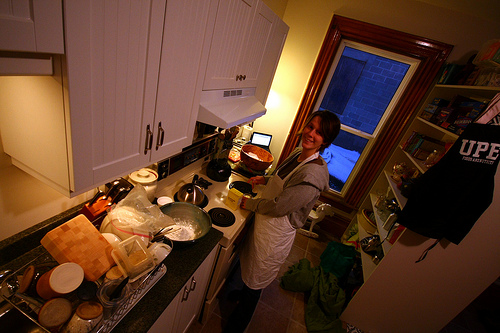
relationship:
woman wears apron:
[224, 105, 342, 332] [237, 144, 321, 289]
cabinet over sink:
[255, 15, 290, 105] [1, 295, 40, 330]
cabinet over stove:
[255, 15, 290, 105] [161, 158, 262, 233]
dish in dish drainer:
[36, 259, 84, 295] [0, 247, 167, 332]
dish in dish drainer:
[110, 233, 154, 278] [0, 247, 167, 332]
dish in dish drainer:
[65, 299, 102, 329] [0, 247, 167, 332]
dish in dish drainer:
[36, 296, 71, 326] [0, 247, 167, 332]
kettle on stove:
[174, 179, 204, 204] [166, 157, 271, 246]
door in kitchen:
[316, 37, 419, 205] [7, 0, 489, 321]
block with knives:
[80, 195, 115, 222] [81, 180, 129, 208]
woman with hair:
[223, 110, 342, 332] [318, 110, 336, 135]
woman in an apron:
[224, 105, 342, 332] [248, 167, 291, 286]